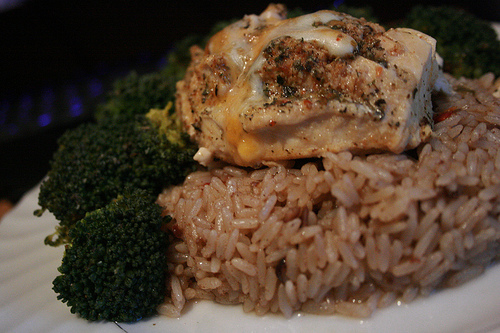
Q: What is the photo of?
A: Food.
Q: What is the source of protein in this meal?
A: Chicken.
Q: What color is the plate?
A: White.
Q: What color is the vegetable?
A: Green.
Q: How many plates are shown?
A: One.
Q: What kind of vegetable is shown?
A: Broccoli.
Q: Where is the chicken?
A: On rice.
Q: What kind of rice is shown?
A: Brown.